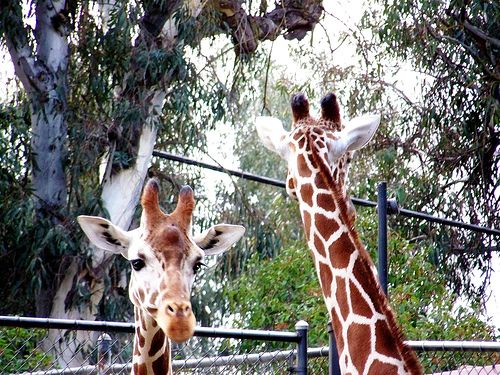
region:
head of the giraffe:
[83, 174, 203, 369]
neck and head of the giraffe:
[287, 92, 425, 371]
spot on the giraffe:
[338, 283, 377, 315]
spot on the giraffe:
[341, 328, 370, 363]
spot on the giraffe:
[328, 240, 348, 262]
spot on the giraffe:
[368, 320, 393, 356]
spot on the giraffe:
[311, 192, 333, 211]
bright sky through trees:
[5, 6, 495, 334]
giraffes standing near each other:
[75, 86, 426, 368]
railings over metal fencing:
[5, 130, 495, 365]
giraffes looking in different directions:
[71, 90, 422, 371]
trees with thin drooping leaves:
[6, 10, 266, 360]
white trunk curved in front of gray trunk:
[10, 0, 195, 365]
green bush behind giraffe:
[245, 210, 491, 355]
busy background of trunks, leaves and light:
[15, 65, 481, 360]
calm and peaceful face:
[71, 170, 246, 345]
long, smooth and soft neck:
[285, 121, 421, 371]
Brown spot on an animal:
[289, 151, 322, 185]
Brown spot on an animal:
[312, 187, 352, 217]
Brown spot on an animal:
[308, 231, 326, 268]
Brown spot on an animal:
[310, 201, 350, 242]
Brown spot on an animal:
[322, 233, 371, 268]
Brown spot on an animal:
[343, 265, 372, 325]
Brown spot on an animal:
[328, 276, 359, 326]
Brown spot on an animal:
[304, 263, 341, 304]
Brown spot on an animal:
[303, 247, 321, 266]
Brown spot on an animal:
[368, 315, 402, 366]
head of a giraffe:
[238, 96, 385, 203]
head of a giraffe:
[248, 80, 383, 159]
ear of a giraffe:
[65, 208, 125, 261]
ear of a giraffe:
[198, 225, 257, 253]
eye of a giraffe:
[123, 249, 148, 271]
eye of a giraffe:
[183, 252, 205, 274]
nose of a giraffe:
[160, 293, 192, 313]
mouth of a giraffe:
[151, 316, 206, 348]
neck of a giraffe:
[126, 333, 176, 373]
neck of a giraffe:
[299, 216, 417, 371]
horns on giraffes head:
[140, 180, 195, 226]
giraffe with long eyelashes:
[193, 256, 210, 275]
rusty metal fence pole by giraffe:
[93, 332, 110, 373]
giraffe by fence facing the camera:
[77, 179, 244, 341]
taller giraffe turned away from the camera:
[249, 88, 384, 207]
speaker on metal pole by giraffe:
[372, 191, 400, 217]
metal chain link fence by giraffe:
[161, 320, 308, 373]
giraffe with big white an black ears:
[77, 213, 136, 252]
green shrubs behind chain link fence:
[0, 324, 57, 372]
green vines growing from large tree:
[252, 12, 288, 119]